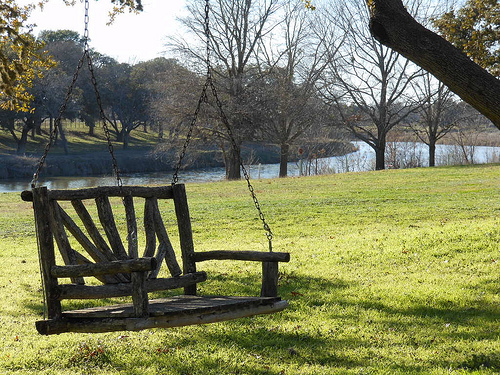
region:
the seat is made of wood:
[32, 143, 307, 328]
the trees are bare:
[188, 27, 318, 164]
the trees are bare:
[260, 25, 350, 133]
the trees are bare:
[341, 10, 395, 140]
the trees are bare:
[209, 15, 297, 101]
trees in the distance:
[63, 50, 150, 120]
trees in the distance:
[147, 48, 226, 129]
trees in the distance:
[238, 58, 330, 128]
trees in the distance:
[105, 44, 185, 129]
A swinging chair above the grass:
[23, 185, 283, 331]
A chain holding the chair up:
[222, 141, 284, 240]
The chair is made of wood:
[46, 263, 157, 323]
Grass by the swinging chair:
[334, 185, 479, 368]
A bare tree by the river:
[337, 70, 409, 169]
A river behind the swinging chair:
[206, 150, 361, 181]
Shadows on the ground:
[298, 284, 336, 361]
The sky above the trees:
[98, 20, 163, 52]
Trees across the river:
[59, 56, 167, 136]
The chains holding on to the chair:
[36, 48, 279, 246]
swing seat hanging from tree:
[22, 0, 284, 323]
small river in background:
[13, 137, 489, 177]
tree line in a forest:
[5, 34, 482, 169]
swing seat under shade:
[26, 3, 288, 330]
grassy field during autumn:
[6, 194, 494, 371]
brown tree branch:
[368, 2, 498, 119]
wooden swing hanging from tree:
[36, 12, 285, 322]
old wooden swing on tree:
[36, 33, 291, 323]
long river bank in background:
[4, 140, 352, 172]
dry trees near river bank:
[198, 56, 463, 173]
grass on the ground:
[309, 198, 356, 238]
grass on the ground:
[391, 161, 453, 214]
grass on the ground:
[266, 178, 333, 232]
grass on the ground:
[341, 206, 427, 277]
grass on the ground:
[6, 247, 43, 285]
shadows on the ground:
[335, 300, 389, 327]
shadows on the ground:
[402, 275, 478, 342]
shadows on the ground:
[221, 318, 307, 365]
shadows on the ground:
[281, 254, 351, 329]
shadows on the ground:
[356, 265, 458, 362]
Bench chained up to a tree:
[23, 155, 308, 345]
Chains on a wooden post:
[168, 55, 245, 216]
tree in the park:
[272, 85, 309, 187]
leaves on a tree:
[10, 35, 54, 108]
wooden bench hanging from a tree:
[30, 144, 319, 337]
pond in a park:
[221, 127, 326, 182]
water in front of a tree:
[194, 143, 257, 204]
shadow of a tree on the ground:
[328, 248, 490, 358]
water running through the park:
[298, 128, 403, 177]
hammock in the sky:
[42, 142, 263, 320]